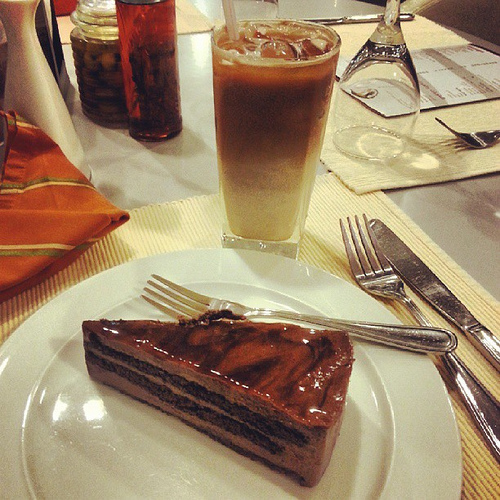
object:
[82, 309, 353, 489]
cake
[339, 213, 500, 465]
fork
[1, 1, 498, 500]
table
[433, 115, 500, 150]
fork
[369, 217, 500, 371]
knife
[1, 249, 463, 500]
plate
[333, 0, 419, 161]
wine glass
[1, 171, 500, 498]
place mat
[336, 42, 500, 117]
menu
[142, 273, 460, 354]
fork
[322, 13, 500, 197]
place mat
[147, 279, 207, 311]
prong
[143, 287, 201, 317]
prong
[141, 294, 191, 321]
prong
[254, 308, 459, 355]
handle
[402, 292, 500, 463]
handle